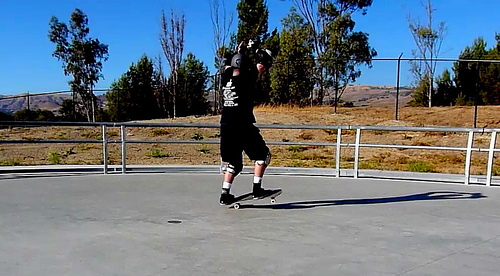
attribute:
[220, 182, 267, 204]
shoes — black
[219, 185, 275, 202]
shoes — black